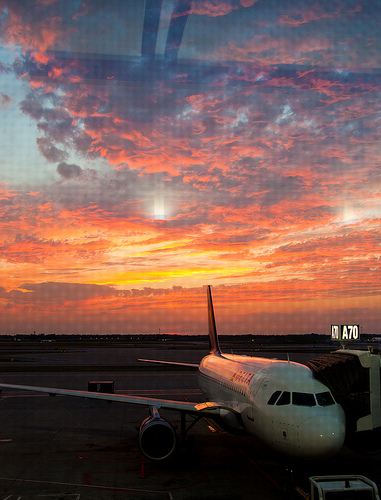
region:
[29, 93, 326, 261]
cloudy red and gray sky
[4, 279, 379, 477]
white airplane parked in an airport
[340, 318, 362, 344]
lighted terminal A70 on airport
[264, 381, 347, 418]
5 dark airplane lights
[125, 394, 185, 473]
large engine on airplane wing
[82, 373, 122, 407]
luggage cart near wing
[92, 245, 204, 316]
bright yellow sun light coming through the clouds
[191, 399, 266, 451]
door opens on side of airplane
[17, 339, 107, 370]
blue lights on airport runway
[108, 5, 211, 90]
two horizontal dark lines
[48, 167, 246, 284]
sky with beautiful colorful sunset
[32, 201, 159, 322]
red and orange clouds at sunset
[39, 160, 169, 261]
purple and red clouds in sky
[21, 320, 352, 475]
airplane parked on runway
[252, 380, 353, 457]
front windows of airplane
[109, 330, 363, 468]
delta passenger airplane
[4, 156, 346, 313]
colorful sky at sunset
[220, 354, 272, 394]
delta logo on side of airplane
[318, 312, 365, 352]
runway number on sign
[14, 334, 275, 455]
long white wings of airplane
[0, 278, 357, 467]
THIS IS A PLANE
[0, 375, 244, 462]
THIS IS A WING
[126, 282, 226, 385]
THIS IS THE PLANE'S TAIL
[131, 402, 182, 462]
THIS IS AN ENGINE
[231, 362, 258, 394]
THE PLANE SAYS DELTA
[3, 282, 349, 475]
THE PLANE IS WHITE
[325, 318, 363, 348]
THE SIGN SAYS A70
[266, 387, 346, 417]
THE PLANE HAS A WINDSHIELD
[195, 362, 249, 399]
THE PLANE HAS MANY WINDOWS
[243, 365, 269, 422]
THIS IS A DOOR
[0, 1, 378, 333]
a beauitful orange and yellow sunset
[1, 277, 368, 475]
A big white airplane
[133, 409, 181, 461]
the right plane engine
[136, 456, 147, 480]
an orange traffic cone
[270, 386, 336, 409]
front windows of a plane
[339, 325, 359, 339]
a sign that says A70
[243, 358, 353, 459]
the nose of a plane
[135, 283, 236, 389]
the back of a plane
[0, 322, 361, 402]
an airport runway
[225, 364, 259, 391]
the word delta in red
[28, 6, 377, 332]
What a beautiful sky!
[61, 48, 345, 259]
the clouds are so unique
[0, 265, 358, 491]
a Delta jet sits on the runway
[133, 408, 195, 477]
the jet engine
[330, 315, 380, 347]
the sign says A70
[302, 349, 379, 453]
the passenger passage way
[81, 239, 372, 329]
the sky is orange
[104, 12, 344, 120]
the sky is grey up here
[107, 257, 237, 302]
this part of the sky is yellow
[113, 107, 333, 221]
the underside of the clouds are pink/orange